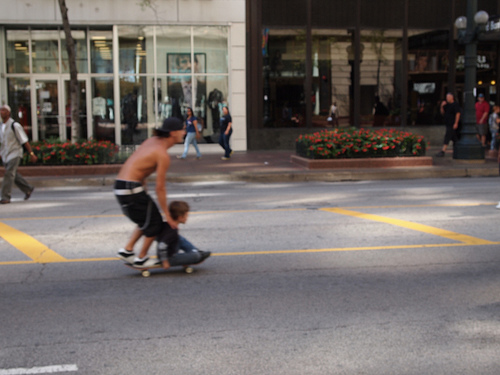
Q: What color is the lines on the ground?
A: Yellow.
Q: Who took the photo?
A: A photographer.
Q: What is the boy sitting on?
A: A skateboard.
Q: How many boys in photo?
A: Two.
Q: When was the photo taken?
A: Daytime.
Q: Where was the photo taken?
A: In the street.